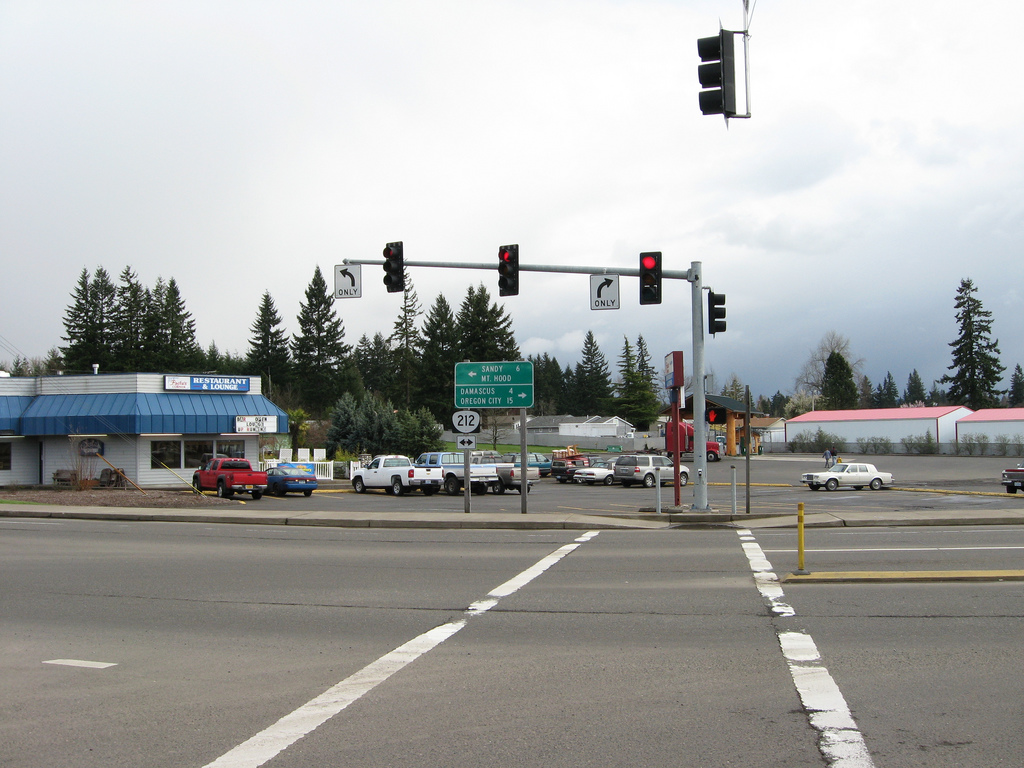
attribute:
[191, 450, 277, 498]
truck — red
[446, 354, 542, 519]
street sign — green and white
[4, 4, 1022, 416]
grey clouds — gray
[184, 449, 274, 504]
pickup truck — red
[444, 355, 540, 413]
road sign — green and white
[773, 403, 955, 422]
roof — red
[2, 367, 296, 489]
building — blue and white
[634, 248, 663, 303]
traffic light — red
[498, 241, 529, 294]
traffic light — red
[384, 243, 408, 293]
traffic light — red